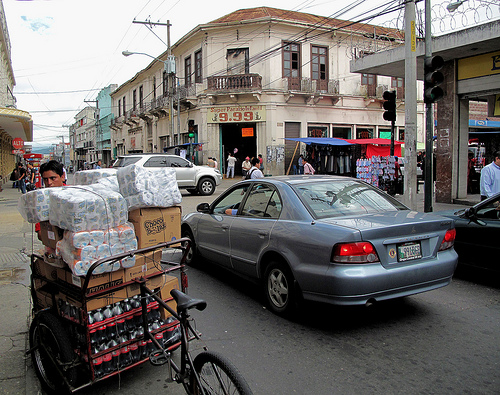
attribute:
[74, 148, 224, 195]
suv — white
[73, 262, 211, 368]
bike — black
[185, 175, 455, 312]
car — gray, blue, grey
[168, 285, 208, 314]
seat — black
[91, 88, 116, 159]
building — green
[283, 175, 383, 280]
car — gray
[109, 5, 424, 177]
building — two story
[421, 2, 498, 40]
barbwire — grey, metal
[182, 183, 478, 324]
suv — silver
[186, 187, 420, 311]
car — light blue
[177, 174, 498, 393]
city street — busy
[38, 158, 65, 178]
hair — black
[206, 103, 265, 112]
letters — red